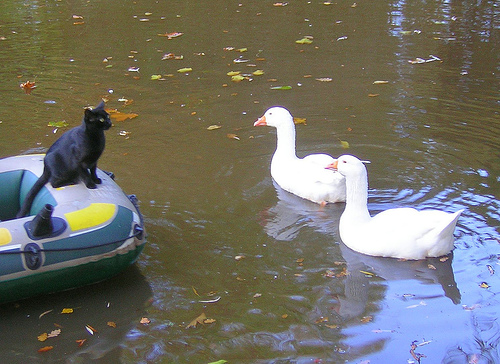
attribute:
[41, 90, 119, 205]
cat — black 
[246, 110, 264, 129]
beak — orange, duck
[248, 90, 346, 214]
duck — one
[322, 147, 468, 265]
duck — one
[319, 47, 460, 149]
pond — one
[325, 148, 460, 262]
duck — one, white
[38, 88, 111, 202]
cat — black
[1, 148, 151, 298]
boat — one, inflatable 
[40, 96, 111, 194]
cat — one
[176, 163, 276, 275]
water — brown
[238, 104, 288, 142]
beak — orange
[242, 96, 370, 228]
goose — white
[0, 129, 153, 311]
raft — green